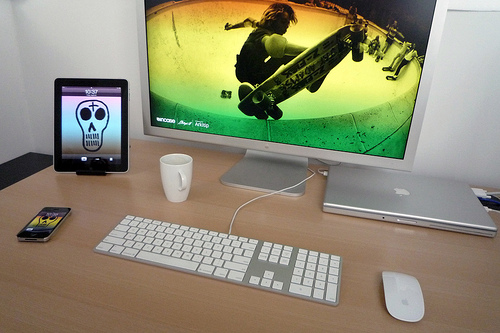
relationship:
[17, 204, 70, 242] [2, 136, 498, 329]
phone on top of desk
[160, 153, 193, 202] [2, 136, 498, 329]
cup on top of desk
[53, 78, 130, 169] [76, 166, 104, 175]
tablet on top of stand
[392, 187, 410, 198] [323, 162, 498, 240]
logo on top of laptop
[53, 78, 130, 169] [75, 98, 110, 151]
tablet has skull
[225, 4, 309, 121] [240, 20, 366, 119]
man jumping on skateboard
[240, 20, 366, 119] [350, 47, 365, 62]
skateboard has wheel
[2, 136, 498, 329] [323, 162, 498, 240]
desk has laptop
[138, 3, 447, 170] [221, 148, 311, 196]
monitor on top of stand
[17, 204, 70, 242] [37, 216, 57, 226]
phone has skull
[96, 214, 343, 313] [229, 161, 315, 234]
keyboard has cord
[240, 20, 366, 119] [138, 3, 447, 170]
skateboard inside of monitor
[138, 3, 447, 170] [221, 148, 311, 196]
monitor has stand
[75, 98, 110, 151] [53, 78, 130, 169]
skull in front of tablet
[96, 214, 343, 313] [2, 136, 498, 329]
keyboard on top of desk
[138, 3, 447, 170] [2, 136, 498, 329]
monitor on top of desk